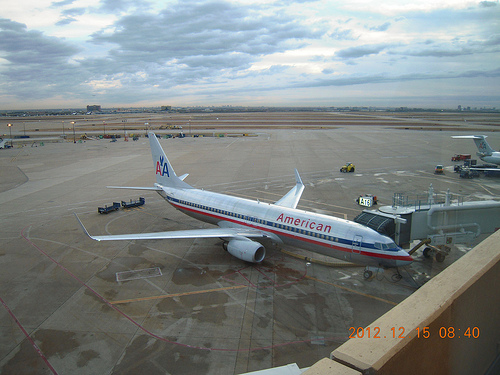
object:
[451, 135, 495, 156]
tail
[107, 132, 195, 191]
tail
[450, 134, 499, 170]
plane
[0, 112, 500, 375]
airport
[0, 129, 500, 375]
runway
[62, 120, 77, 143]
lights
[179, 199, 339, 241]
windows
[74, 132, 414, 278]
airplane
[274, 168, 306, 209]
wing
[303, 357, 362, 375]
wall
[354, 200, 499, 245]
corridor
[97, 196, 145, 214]
luggage carrier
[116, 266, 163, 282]
square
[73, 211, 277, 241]
wing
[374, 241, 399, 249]
window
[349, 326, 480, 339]
timestamp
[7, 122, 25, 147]
lights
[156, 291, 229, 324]
spots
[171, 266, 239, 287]
spots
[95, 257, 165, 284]
spots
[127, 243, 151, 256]
spots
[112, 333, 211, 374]
spots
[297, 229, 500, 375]
building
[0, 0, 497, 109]
clouds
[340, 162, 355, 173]
vehicle